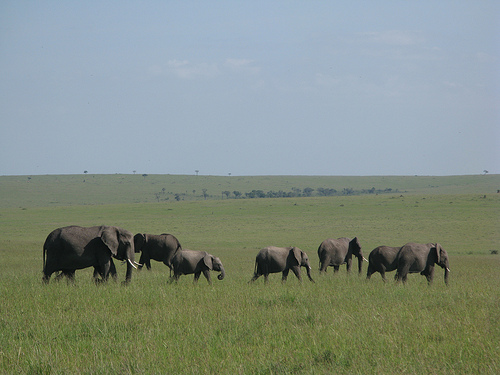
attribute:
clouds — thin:
[53, 25, 485, 167]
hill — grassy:
[11, 159, 248, 213]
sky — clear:
[12, 24, 457, 171]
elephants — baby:
[168, 242, 225, 284]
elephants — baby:
[247, 240, 312, 280]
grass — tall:
[2, 175, 499, 372]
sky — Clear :
[115, 28, 450, 178]